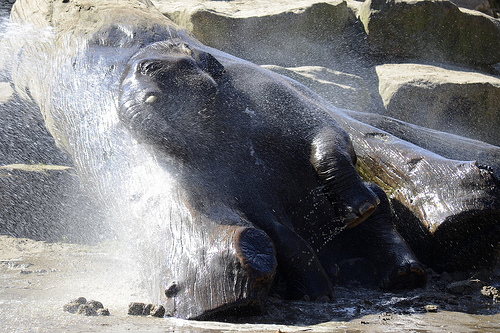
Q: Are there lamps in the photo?
A: No, there are no lamps.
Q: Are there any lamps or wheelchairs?
A: No, there are no lamps or wheelchairs.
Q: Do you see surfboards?
A: No, there are no surfboards.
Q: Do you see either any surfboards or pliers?
A: No, there are no surfboards or pliers.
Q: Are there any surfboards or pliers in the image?
A: No, there are no surfboards or pliers.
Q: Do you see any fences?
A: No, there are no fences.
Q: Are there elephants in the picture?
A: Yes, there is an elephant.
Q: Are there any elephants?
A: Yes, there is an elephant.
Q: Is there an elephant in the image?
A: Yes, there is an elephant.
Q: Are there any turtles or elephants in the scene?
A: Yes, there is an elephant.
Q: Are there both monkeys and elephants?
A: No, there is an elephant but no monkeys.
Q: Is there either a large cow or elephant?
A: Yes, there is a large elephant.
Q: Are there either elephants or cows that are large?
A: Yes, the elephant is large.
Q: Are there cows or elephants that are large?
A: Yes, the elephant is large.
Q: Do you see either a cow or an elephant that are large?
A: Yes, the elephant is large.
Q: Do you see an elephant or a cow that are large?
A: Yes, the elephant is large.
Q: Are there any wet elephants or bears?
A: Yes, there is a wet elephant.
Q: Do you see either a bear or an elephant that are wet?
A: Yes, the elephant is wet.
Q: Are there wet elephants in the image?
A: Yes, there is a wet elephant.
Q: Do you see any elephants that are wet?
A: Yes, there is an elephant that is wet.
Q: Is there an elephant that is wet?
A: Yes, there is an elephant that is wet.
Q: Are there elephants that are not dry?
A: Yes, there is a wet elephant.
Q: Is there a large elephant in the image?
A: Yes, there is a large elephant.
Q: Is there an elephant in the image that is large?
A: Yes, there is an elephant that is large.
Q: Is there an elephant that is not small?
A: Yes, there is a large elephant.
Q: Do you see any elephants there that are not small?
A: Yes, there is a large elephant.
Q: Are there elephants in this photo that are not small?
A: Yes, there is a large elephant.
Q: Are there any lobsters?
A: No, there are no lobsters.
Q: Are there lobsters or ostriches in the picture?
A: No, there are no lobsters or ostriches.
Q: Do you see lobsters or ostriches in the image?
A: No, there are no lobsters or ostriches.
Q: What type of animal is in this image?
A: The animal is an elephant.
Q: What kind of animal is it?
A: The animal is an elephant.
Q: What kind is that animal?
A: That is an elephant.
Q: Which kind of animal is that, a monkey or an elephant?
A: That is an elephant.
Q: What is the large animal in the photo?
A: The animal is an elephant.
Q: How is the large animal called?
A: The animal is an elephant.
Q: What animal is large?
A: The animal is an elephant.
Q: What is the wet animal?
A: The animal is an elephant.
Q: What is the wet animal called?
A: The animal is an elephant.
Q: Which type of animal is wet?
A: The animal is an elephant.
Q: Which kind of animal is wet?
A: The animal is an elephant.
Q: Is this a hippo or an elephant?
A: This is an elephant.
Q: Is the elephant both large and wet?
A: Yes, the elephant is large and wet.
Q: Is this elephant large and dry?
A: No, the elephant is large but wet.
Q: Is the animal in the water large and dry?
A: No, the elephant is large but wet.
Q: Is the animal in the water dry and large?
A: No, the elephant is large but wet.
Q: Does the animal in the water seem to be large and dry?
A: No, the elephant is large but wet.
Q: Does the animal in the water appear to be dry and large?
A: No, the elephant is large but wet.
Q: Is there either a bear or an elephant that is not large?
A: No, there is an elephant but it is large.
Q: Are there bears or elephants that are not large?
A: No, there is an elephant but it is large.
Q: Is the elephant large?
A: Yes, the elephant is large.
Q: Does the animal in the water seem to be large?
A: Yes, the elephant is large.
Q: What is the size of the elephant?
A: The elephant is large.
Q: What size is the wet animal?
A: The elephant is large.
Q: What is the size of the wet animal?
A: The elephant is large.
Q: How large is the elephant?
A: The elephant is large.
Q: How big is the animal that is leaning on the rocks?
A: The elephant is large.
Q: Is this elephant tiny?
A: No, the elephant is large.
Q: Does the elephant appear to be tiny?
A: No, the elephant is large.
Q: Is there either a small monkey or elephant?
A: No, there is an elephant but it is large.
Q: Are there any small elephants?
A: No, there is an elephant but it is large.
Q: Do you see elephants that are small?
A: No, there is an elephant but it is large.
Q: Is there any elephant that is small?
A: No, there is an elephant but it is large.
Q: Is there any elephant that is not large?
A: No, there is an elephant but it is large.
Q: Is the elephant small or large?
A: The elephant is large.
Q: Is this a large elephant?
A: Yes, this is a large elephant.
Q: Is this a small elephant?
A: No, this is a large elephant.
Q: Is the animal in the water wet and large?
A: Yes, the elephant is wet and large.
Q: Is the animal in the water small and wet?
A: No, the elephant is wet but large.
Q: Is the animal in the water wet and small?
A: No, the elephant is wet but large.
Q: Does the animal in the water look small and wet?
A: No, the elephant is wet but large.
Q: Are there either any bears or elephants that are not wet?
A: No, there is an elephant but it is wet.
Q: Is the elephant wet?
A: Yes, the elephant is wet.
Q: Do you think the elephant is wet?
A: Yes, the elephant is wet.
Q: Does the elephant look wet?
A: Yes, the elephant is wet.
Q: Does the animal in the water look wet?
A: Yes, the elephant is wet.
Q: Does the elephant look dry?
A: No, the elephant is wet.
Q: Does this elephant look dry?
A: No, the elephant is wet.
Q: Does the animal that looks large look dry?
A: No, the elephant is wet.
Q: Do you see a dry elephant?
A: No, there is an elephant but it is wet.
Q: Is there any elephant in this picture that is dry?
A: No, there is an elephant but it is wet.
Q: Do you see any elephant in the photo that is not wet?
A: No, there is an elephant but it is wet.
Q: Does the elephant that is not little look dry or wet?
A: The elephant is wet.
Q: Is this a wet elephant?
A: Yes, this is a wet elephant.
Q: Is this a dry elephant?
A: No, this is a wet elephant.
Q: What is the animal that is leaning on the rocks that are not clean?
A: The animal is an elephant.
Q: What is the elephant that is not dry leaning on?
A: The elephant is leaning on the rocks.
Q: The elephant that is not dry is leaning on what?
A: The elephant is leaning on the rocks.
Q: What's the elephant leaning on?
A: The elephant is leaning on the rocks.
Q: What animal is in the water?
A: The elephant is in the water.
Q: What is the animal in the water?
A: The animal is an elephant.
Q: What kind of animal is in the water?
A: The animal is an elephant.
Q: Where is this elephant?
A: The elephant is in the water.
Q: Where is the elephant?
A: The elephant is in the water.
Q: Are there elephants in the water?
A: Yes, there is an elephant in the water.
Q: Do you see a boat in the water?
A: No, there is an elephant in the water.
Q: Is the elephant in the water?
A: Yes, the elephant is in the water.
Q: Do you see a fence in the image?
A: No, there are no fences.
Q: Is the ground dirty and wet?
A: Yes, the ground is dirty and wet.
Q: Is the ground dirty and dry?
A: No, the ground is dirty but wet.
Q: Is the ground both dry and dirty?
A: No, the ground is dirty but wet.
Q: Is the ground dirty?
A: Yes, the ground is dirty.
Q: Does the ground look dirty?
A: Yes, the ground is dirty.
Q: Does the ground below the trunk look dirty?
A: Yes, the ground is dirty.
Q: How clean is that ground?
A: The ground is dirty.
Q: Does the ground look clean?
A: No, the ground is dirty.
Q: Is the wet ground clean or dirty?
A: The ground is dirty.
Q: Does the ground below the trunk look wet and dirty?
A: Yes, the ground is wet and dirty.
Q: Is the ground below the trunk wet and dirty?
A: Yes, the ground is wet and dirty.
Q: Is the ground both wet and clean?
A: No, the ground is wet but dirty.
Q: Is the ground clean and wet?
A: No, the ground is wet but dirty.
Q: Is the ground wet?
A: Yes, the ground is wet.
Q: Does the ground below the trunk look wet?
A: Yes, the ground is wet.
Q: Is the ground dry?
A: No, the ground is wet.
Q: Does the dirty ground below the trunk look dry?
A: No, the ground is wet.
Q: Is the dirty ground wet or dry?
A: The ground is wet.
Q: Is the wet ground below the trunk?
A: Yes, the ground is below the trunk.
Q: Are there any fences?
A: No, there are no fences.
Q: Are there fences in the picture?
A: No, there are no fences.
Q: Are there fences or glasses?
A: No, there are no fences or glasses.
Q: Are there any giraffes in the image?
A: No, there are no giraffes.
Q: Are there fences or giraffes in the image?
A: No, there are no giraffes or fences.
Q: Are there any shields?
A: No, there are no shields.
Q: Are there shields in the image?
A: No, there are no shields.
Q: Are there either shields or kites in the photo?
A: No, there are no shields or kites.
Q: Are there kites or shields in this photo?
A: No, there are no shields or kites.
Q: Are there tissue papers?
A: No, there are no tissue papers.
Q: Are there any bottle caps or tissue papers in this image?
A: No, there are no tissue papers or bottle caps.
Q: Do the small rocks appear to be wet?
A: Yes, the rocks are wet.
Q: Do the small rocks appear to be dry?
A: No, the rocks are wet.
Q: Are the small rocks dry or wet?
A: The rocks are wet.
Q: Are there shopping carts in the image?
A: No, there are no shopping carts.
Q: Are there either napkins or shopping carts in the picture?
A: No, there are no shopping carts or napkins.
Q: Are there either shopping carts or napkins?
A: No, there are no shopping carts or napkins.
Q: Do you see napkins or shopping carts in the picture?
A: No, there are no shopping carts or napkins.